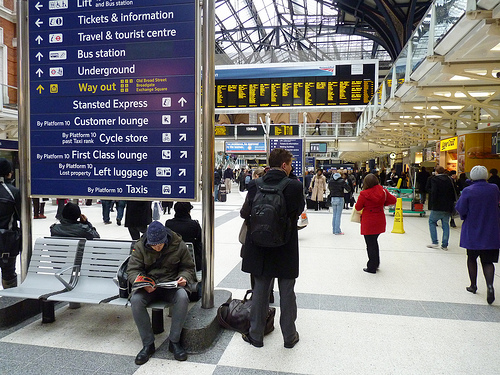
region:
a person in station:
[236, 149, 321, 336]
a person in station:
[103, 208, 195, 323]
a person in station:
[455, 167, 485, 213]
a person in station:
[432, 169, 450, 236]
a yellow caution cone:
[383, 197, 428, 259]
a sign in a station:
[5, 13, 235, 313]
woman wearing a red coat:
[350, 173, 398, 275]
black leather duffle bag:
[216, 288, 276, 335]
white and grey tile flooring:
[1, 180, 498, 372]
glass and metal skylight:
[214, 0, 396, 64]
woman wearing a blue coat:
[452, 163, 499, 307]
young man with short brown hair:
[238, 146, 306, 348]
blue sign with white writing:
[29, 0, 196, 201]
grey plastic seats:
[1, 238, 198, 308]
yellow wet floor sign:
[389, 198, 405, 235]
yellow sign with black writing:
[438, 137, 456, 152]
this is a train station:
[31, 27, 483, 339]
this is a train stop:
[192, 64, 397, 292]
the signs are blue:
[37, 35, 214, 220]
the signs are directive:
[44, 27, 209, 212]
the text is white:
[11, 64, 218, 241]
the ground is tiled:
[335, 294, 442, 359]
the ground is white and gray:
[327, 270, 457, 364]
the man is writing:
[110, 207, 248, 358]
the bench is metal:
[32, 218, 149, 286]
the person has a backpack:
[225, 180, 375, 305]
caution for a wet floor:
[390, 189, 402, 234]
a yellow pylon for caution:
[391, 198, 405, 237]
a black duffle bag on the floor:
[226, 281, 276, 336]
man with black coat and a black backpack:
[237, 139, 307, 344]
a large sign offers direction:
[19, 0, 201, 198]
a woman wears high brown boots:
[458, 254, 498, 309]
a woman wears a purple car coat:
[452, 179, 499, 251]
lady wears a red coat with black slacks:
[348, 171, 399, 275]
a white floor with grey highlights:
[1, 175, 496, 374]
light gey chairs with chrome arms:
[0, 230, 120, 319]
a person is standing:
[343, 165, 402, 285]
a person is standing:
[423, 158, 455, 274]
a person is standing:
[453, 161, 498, 323]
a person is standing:
[303, 167, 335, 226]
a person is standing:
[51, 198, 106, 236]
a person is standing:
[113, 194, 162, 235]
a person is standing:
[100, 185, 123, 226]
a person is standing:
[1, 155, 33, 284]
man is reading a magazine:
[102, 206, 199, 356]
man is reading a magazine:
[111, 208, 193, 364]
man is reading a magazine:
[110, 203, 194, 370]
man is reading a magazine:
[123, 211, 199, 353]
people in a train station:
[2, 112, 495, 362]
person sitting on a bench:
[4, 216, 207, 373]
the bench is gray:
[4, 229, 132, 322]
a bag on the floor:
[218, 280, 283, 344]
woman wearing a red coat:
[347, 169, 404, 278]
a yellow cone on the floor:
[386, 193, 409, 239]